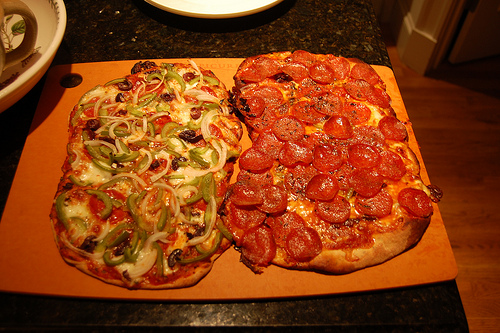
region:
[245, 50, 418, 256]
lots of pepperoni slices on a pizza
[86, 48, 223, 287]
olives, green peppers and onions on a pizza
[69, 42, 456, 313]
two homemade pizza with an oval shape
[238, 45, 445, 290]
a homemade pizza with pepperoni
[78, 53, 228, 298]
a homemade pizza with green peppers, onions and black olives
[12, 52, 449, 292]
a wooden tray with two pizzas on it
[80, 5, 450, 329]
a dark marble counter top with two pizzas on it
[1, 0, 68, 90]
a white bowl with green foliage painted on it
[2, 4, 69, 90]
a white cup in a white bowl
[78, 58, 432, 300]
two pizzas on a tray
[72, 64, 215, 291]
a supreme pizza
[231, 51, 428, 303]
a pepporoni pizza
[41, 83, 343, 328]
a trey of pizza on a counter top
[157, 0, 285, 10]
a white plate on the table top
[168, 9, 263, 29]
the tan part around the plate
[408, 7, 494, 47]
the corner of the door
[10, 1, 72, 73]
a plate on the counter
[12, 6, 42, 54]
the handle of the tea pot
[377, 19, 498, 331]
Wooden flooring.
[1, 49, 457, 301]
A wooden slab with two pizzas resting on it.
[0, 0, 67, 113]
A bowl with a cup inside it.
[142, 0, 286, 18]
A plate.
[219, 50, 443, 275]
An unusually shaped pepperoni pizza.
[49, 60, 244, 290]
A pizza with onion, olive, pepperoni, and green pepper.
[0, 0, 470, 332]
A countertop with stuff on it.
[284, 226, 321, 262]
A slice of pepperoni.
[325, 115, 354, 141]
A slice of pepperoni.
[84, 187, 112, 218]
A slice of green pepper.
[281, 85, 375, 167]
Pepperoni on this pizza.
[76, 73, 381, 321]
A brown carving board holding two pizzas.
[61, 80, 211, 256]
A pizza with many toppings.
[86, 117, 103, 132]
A sliced black olive.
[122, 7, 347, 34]
A light above the pizzas.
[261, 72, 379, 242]
The cheese is below the pepperoni.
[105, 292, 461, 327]
A black counter top.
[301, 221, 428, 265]
Brown crust.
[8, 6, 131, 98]
A white bowl in the background.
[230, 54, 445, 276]
a large pepperoni pizza with cheese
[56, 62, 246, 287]
big vegetarian pizza with cheese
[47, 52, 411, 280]
two large pizzas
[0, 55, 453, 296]
a wooden cutting board with two pizzas on it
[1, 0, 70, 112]
a white colored bowl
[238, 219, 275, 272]
piece of pepperoni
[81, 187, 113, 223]
a green pepper slice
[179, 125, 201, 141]
sliced black olive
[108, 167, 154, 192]
sliced white onion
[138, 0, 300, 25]
the edge of a plate